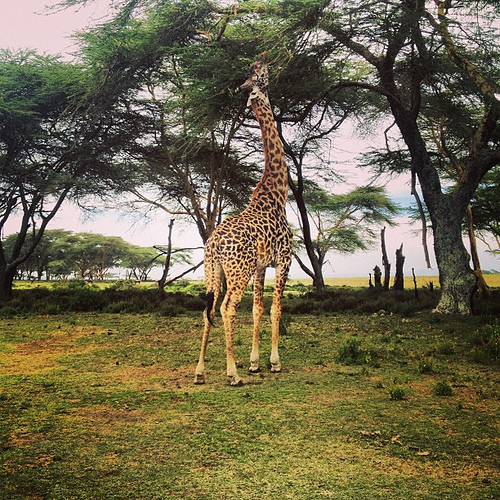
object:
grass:
[327, 316, 384, 369]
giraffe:
[191, 49, 295, 386]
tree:
[0, 47, 143, 315]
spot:
[267, 231, 272, 239]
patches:
[329, 373, 361, 389]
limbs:
[269, 255, 292, 373]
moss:
[431, 247, 475, 315]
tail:
[207, 248, 217, 330]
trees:
[162, 0, 500, 315]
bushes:
[0, 282, 202, 317]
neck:
[251, 104, 288, 208]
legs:
[193, 251, 220, 385]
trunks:
[291, 133, 326, 287]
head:
[233, 50, 274, 109]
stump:
[392, 242, 406, 291]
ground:
[2, 385, 497, 500]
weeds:
[337, 332, 366, 364]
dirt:
[25, 324, 80, 365]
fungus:
[372, 309, 387, 318]